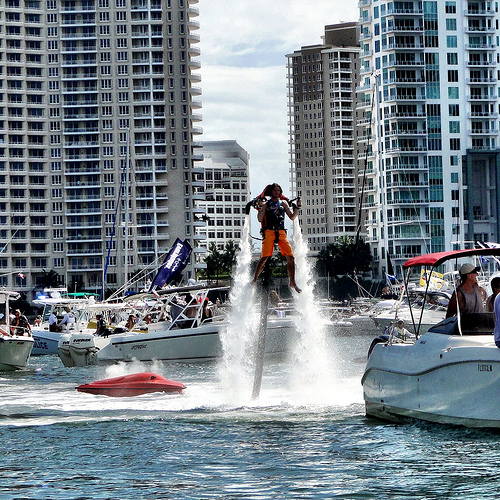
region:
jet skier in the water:
[222, 167, 324, 329]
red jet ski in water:
[77, 362, 201, 415]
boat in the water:
[353, 228, 494, 453]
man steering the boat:
[434, 258, 496, 328]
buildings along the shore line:
[10, 4, 207, 259]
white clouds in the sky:
[217, 64, 277, 108]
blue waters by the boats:
[43, 435, 320, 493]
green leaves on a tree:
[317, 239, 377, 274]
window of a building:
[444, 117, 461, 134]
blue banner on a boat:
[137, 237, 202, 296]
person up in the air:
[239, 177, 303, 302]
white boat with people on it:
[356, 244, 498, 459]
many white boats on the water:
[16, 274, 476, 374]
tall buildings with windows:
[289, 20, 496, 261]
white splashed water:
[231, 219, 273, 416]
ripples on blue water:
[10, 414, 441, 496]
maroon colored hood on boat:
[401, 230, 498, 284]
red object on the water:
[80, 370, 190, 407]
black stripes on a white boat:
[104, 334, 250, 371]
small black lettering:
[474, 361, 494, 376]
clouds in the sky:
[229, 34, 278, 114]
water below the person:
[235, 422, 301, 478]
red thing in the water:
[96, 361, 183, 411]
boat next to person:
[342, 310, 452, 410]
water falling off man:
[220, 310, 330, 370]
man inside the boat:
[425, 255, 485, 330]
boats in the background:
[25, 276, 165, 381]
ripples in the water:
[215, 436, 345, 476]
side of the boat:
[383, 345, 453, 395]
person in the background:
[9, 300, 41, 341]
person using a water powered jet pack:
[243, 183, 301, 293]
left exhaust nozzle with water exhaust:
[286, 202, 341, 402]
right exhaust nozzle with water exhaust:
[214, 200, 256, 404]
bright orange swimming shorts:
[260, 228, 293, 256]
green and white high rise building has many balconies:
[355, 0, 499, 290]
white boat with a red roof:
[361, 247, 499, 426]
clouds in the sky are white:
[188, 0, 360, 250]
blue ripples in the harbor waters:
[0, 337, 499, 499]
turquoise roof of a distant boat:
[61, 292, 99, 298]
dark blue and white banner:
[148, 237, 190, 292]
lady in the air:
[216, 161, 320, 307]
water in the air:
[217, 322, 351, 382]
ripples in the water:
[208, 433, 265, 468]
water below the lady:
[231, 416, 303, 465]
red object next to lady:
[118, 363, 190, 399]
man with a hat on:
[441, 257, 487, 317]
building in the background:
[36, 156, 115, 213]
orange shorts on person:
[244, 227, 302, 274]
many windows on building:
[50, 48, 150, 158]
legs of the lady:
[243, 260, 318, 297]